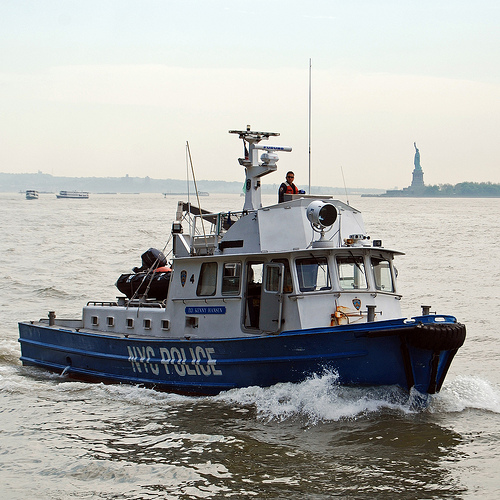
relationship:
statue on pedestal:
[412, 141, 422, 171] [412, 170, 426, 192]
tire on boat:
[412, 320, 466, 350] [16, 126, 466, 402]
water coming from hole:
[59, 364, 70, 378] [64, 355, 72, 368]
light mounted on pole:
[305, 199, 339, 229] [320, 227, 327, 241]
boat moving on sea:
[16, 126, 466, 402] [2, 195, 498, 500]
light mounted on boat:
[305, 199, 339, 229] [16, 126, 466, 402]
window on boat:
[223, 258, 243, 299] [16, 126, 466, 402]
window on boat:
[295, 258, 334, 295] [16, 126, 466, 402]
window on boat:
[338, 256, 369, 291] [16, 126, 466, 402]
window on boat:
[371, 258, 396, 292] [16, 126, 466, 402]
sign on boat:
[126, 345, 224, 377] [16, 126, 466, 402]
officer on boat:
[277, 171, 300, 204] [16, 126, 466, 402]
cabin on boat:
[164, 197, 405, 341] [16, 126, 466, 402]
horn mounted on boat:
[351, 234, 372, 248] [16, 126, 466, 402]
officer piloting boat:
[277, 171, 300, 204] [16, 126, 466, 402]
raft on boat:
[117, 274, 172, 300] [16, 126, 466, 402]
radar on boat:
[254, 143, 294, 164] [16, 126, 466, 402]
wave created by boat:
[218, 359, 500, 439] [16, 126, 466, 402]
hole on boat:
[64, 355, 72, 368] [16, 126, 466, 402]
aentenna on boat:
[307, 58, 314, 196] [16, 126, 466, 402]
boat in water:
[16, 126, 466, 402] [59, 364, 70, 378]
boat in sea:
[16, 126, 466, 402] [2, 195, 498, 500]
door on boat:
[258, 260, 283, 335] [16, 126, 466, 402]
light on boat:
[305, 199, 339, 229] [16, 126, 466, 402]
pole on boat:
[186, 139, 208, 238] [16, 126, 466, 402]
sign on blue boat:
[126, 345, 224, 377] [16, 126, 466, 402]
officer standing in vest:
[277, 171, 300, 204] [282, 180, 301, 198]